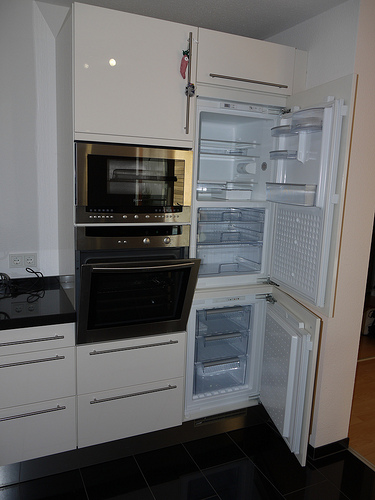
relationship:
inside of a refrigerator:
[199, 112, 272, 400] [186, 69, 362, 473]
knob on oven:
[163, 236, 173, 246] [71, 221, 199, 345]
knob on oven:
[142, 236, 151, 246] [71, 221, 199, 345]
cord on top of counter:
[0, 265, 47, 307] [2, 273, 77, 335]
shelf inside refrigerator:
[199, 147, 267, 165] [186, 69, 362, 473]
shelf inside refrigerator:
[195, 180, 261, 194] [186, 69, 362, 473]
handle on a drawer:
[204, 307, 246, 315] [197, 307, 254, 339]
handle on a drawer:
[201, 330, 243, 345] [193, 330, 251, 364]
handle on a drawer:
[203, 358, 243, 374] [195, 357, 250, 397]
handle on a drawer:
[86, 380, 181, 405] [77, 373, 192, 449]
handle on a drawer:
[85, 336, 181, 359] [78, 329, 194, 400]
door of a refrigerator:
[267, 71, 362, 322] [186, 69, 362, 473]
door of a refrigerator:
[254, 282, 324, 472] [186, 69, 362, 473]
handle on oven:
[92, 266, 193, 271] [71, 221, 199, 345]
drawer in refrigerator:
[197, 307, 254, 339] [186, 69, 362, 473]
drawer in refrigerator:
[193, 330, 251, 364] [186, 69, 362, 473]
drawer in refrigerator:
[195, 357, 250, 397] [186, 69, 362, 473]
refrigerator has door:
[186, 69, 362, 473] [267, 71, 362, 322]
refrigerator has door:
[186, 69, 362, 473] [254, 282, 324, 472]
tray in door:
[263, 179, 316, 211] [267, 71, 362, 322]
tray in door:
[267, 147, 301, 168] [267, 71, 362, 322]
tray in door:
[266, 122, 298, 140] [267, 71, 362, 322]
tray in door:
[293, 117, 329, 137] [267, 71, 362, 322]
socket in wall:
[7, 250, 39, 271] [2, 0, 60, 284]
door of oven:
[73, 253, 205, 341] [71, 221, 199, 345]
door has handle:
[73, 253, 205, 341] [92, 266, 193, 271]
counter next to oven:
[2, 273, 77, 335] [71, 221, 199, 345]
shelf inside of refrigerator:
[199, 147, 267, 165] [186, 69, 362, 473]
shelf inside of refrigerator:
[195, 180, 261, 194] [186, 69, 362, 473]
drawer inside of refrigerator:
[197, 307, 254, 339] [186, 69, 362, 473]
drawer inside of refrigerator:
[193, 330, 251, 364] [186, 69, 362, 473]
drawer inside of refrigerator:
[195, 357, 250, 397] [186, 69, 362, 473]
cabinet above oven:
[65, 2, 201, 140] [75, 138, 201, 345]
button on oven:
[86, 214, 93, 221] [75, 138, 201, 345]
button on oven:
[92, 215, 96, 219] [75, 138, 201, 345]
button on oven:
[97, 213, 100, 219] [75, 138, 201, 345]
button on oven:
[102, 214, 106, 219] [75, 138, 201, 345]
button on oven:
[106, 216, 110, 219] [75, 138, 201, 345]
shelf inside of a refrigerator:
[199, 147, 267, 165] [186, 69, 362, 473]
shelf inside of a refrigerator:
[195, 180, 261, 194] [186, 69, 362, 473]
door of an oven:
[73, 253, 205, 341] [71, 221, 199, 345]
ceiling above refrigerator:
[69, 2, 346, 40] [186, 69, 362, 473]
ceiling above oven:
[69, 2, 346, 40] [71, 221, 199, 345]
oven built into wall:
[71, 221, 199, 345] [2, 0, 60, 284]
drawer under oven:
[77, 373, 192, 449] [71, 221, 199, 345]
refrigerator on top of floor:
[186, 69, 362, 473] [4, 416, 373, 500]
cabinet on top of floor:
[1, 317, 82, 470] [4, 416, 373, 500]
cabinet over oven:
[65, 2, 201, 140] [71, 221, 199, 345]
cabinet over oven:
[65, 2, 201, 140] [75, 138, 201, 345]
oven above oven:
[75, 138, 201, 345] [71, 221, 199, 345]